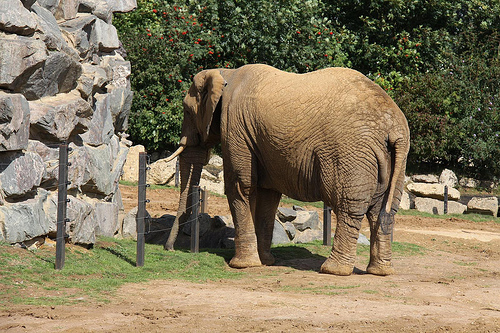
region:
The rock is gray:
[2, 200, 56, 240]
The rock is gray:
[0, 160, 45, 195]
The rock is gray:
[0, 91, 30, 147]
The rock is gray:
[30, 92, 87, 134]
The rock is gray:
[41, 147, 89, 182]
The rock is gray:
[53, 191, 90, 241]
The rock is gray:
[82, 95, 113, 140]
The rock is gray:
[77, 62, 107, 95]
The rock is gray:
[120, 205, 155, 240]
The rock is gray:
[275, 200, 298, 221]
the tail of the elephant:
[378, 139, 403, 237]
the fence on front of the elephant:
[46, 137, 203, 273]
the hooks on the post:
[60, 145, 77, 241]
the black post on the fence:
[54, 140, 75, 274]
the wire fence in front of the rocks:
[0, 142, 58, 273]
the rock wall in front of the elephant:
[0, 0, 137, 226]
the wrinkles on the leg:
[321, 143, 371, 272]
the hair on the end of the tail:
[378, 209, 394, 233]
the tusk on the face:
[163, 142, 183, 166]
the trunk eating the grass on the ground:
[178, 153, 206, 254]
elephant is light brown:
[164, 67, 431, 269]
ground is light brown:
[375, 252, 470, 332]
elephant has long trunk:
[137, 159, 193, 257]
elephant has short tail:
[361, 115, 426, 228]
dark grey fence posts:
[40, 159, 150, 270]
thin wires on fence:
[63, 138, 203, 246]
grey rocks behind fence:
[3, 1, 178, 245]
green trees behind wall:
[140, 9, 490, 169]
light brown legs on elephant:
[225, 160, 352, 263]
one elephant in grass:
[157, 52, 437, 282]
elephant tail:
[372, 128, 409, 254]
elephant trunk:
[158, 152, 193, 265]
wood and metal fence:
[6, 140, 219, 265]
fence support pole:
[128, 144, 164, 276]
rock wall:
[5, 2, 126, 242]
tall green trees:
[129, 4, 489, 172]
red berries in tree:
[139, 2, 216, 61]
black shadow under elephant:
[130, 192, 359, 299]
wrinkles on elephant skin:
[309, 132, 368, 175]